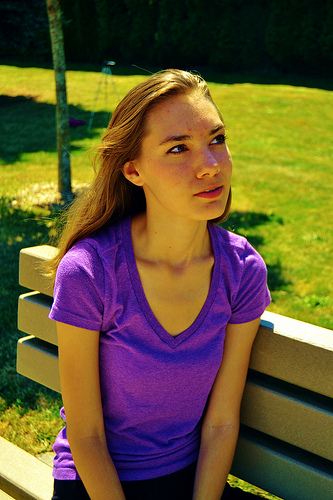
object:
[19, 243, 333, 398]
top of bench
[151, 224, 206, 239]
line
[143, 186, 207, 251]
woman's neck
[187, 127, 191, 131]
acne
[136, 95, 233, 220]
girl's face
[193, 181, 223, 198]
red lipstick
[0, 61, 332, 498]
grass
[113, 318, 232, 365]
break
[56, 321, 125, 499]
arm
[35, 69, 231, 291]
hair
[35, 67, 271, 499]
girl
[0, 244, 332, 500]
bench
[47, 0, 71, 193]
trunk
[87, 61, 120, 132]
tripod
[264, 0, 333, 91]
tree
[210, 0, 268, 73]
tree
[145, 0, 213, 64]
tree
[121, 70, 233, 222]
girl's head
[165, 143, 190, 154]
eye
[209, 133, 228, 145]
eye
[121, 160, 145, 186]
right ear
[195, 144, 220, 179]
nose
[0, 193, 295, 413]
shadow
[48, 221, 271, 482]
purple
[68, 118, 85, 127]
purple thing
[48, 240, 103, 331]
sleeve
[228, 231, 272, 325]
sleeve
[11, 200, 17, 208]
flower